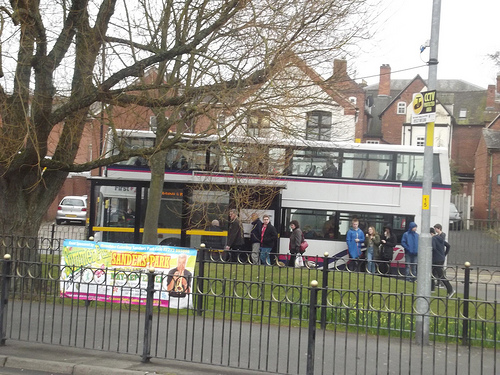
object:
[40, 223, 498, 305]
road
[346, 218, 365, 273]
boy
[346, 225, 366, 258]
jacket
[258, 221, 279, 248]
black coat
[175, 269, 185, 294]
trumpet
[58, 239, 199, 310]
banner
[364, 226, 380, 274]
girl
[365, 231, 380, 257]
jacket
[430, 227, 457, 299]
man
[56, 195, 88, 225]
car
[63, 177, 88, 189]
brick wall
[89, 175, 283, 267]
bus stop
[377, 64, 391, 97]
chimney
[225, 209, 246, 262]
man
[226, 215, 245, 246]
jacket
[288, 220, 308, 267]
person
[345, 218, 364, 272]
person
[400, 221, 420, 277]
person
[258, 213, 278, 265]
person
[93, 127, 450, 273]
bus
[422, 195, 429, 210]
sticker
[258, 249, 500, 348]
fence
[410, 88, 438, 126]
sign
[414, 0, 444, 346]
lamp post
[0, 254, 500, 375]
fence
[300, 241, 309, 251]
purse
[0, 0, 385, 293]
tree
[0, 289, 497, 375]
road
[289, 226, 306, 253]
coat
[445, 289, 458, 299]
shoes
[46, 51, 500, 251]
building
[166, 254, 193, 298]
man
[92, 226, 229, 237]
stripe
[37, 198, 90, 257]
driveway